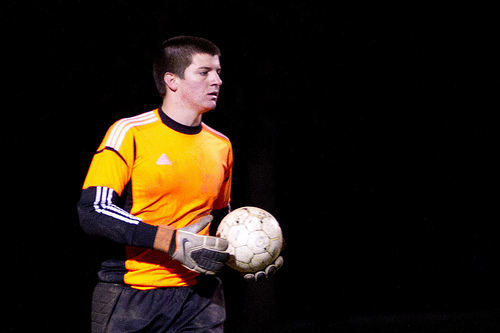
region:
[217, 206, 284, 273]
white official sized soccer ball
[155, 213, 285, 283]
goalies hands in thick padded gloves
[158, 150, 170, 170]
adidas logo on shirt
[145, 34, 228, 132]
goal keepers head and face with focused look on face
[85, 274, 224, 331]
dusty black shorts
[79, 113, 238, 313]
yellow and black adidas goalie shirt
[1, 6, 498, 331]
solid black background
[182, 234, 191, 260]
nike logo on goalies gloves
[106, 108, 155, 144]
triple white adidas stripes on shoulders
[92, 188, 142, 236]
triple white adidas stripes on arm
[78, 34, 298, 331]
this is a man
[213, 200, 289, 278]
this is a ball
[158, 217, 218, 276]
this is a glove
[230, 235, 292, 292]
this is a glove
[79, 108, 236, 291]
the shirt is orange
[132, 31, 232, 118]
the head of a man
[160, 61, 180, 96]
the ear of a man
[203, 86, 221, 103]
the mouth of a man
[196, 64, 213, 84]
the eye of a man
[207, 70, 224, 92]
the nose of a man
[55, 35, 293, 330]
a soccer player holding a ball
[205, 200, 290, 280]
soccer ball is white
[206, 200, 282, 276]
soccer ball has hexagon shapes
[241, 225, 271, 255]
hexagon shape of soccer ball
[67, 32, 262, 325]
player wears an orange shirt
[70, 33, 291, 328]
soccer-keeper wears gloves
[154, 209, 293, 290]
two heavy duty gloves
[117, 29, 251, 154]
man has short hair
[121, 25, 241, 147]
man has black hair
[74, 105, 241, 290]
white stripes on shoulder of shirt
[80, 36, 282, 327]
Man playing soccer ball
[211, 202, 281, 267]
Soccer ball in man's hand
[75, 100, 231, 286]
Man wearing gold, black and white top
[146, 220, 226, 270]
Soccer player's right glove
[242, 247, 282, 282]
Left glove of soccer player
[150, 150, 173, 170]
Logo on gold tee shirt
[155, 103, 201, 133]
Black trim around neck of gold shirt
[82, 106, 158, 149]
White strip on shoulder of shirt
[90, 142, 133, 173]
Black strip around the sleeve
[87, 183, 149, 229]
Three white strips on black sleeve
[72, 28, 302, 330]
soccer player holding a ball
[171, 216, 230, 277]
black and gray glove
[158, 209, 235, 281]
glove on the hand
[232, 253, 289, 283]
fingers under the ball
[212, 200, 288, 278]
white soccer ball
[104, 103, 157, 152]
white lines on the shoulder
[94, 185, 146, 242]
white lines on the blue sleeve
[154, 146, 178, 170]
white Addidas symbol on the jersey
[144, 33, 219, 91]
short brown hair on the head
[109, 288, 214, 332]
wrinkles on the pants